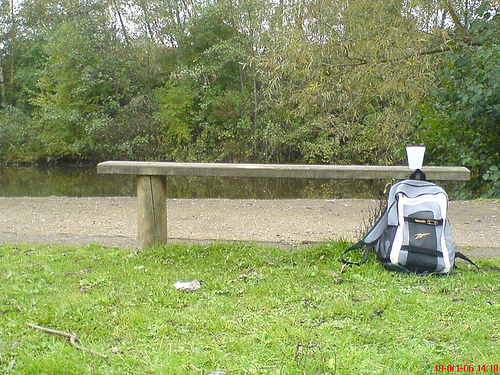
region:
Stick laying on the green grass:
[12, 302, 131, 369]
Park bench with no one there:
[88, 8, 494, 298]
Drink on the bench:
[370, 115, 450, 170]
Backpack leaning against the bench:
[362, 170, 467, 290]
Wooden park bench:
[90, 140, 491, 265]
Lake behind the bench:
[4, 108, 370, 219]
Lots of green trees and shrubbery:
[9, 13, 461, 181]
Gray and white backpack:
[370, 176, 462, 298]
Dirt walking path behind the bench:
[6, 183, 496, 250]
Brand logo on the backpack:
[400, 203, 449, 243]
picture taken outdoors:
[57, 55, 404, 362]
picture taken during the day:
[58, 21, 464, 317]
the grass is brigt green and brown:
[115, 278, 270, 358]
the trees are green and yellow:
[177, 59, 336, 134]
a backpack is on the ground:
[352, 174, 494, 282]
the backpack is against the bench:
[354, 187, 493, 269]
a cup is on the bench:
[387, 79, 424, 169]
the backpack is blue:
[364, 149, 456, 282]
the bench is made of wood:
[101, 143, 248, 288]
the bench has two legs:
[111, 148, 478, 293]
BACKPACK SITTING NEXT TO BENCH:
[350, 176, 465, 281]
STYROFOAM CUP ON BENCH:
[397, 142, 437, 175]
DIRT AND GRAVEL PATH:
[4, 189, 497, 254]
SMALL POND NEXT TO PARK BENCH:
[3, 157, 387, 200]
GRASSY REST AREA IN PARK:
[5, 239, 496, 371]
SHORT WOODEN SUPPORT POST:
[130, 172, 177, 252]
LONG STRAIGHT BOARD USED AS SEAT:
[87, 149, 472, 191]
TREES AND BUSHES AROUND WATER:
[5, 8, 493, 177]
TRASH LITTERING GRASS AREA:
[161, 270, 216, 297]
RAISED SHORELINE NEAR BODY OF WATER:
[40, 155, 97, 172]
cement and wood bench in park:
[82, 142, 474, 277]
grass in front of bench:
[25, 225, 485, 342]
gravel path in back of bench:
[11, 182, 491, 242]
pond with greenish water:
[0, 145, 335, 200]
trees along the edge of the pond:
[1, 0, 492, 150]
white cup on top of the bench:
[386, 131, 456, 171]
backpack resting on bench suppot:
[360, 166, 470, 281]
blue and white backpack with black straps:
[330, 180, 470, 285]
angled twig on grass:
[16, 297, 126, 363]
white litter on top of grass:
[155, 270, 236, 320]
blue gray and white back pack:
[330, 178, 452, 331]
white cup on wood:
[386, 133, 429, 176]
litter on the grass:
[140, 269, 220, 316]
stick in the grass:
[19, 296, 111, 373]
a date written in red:
[424, 358, 479, 373]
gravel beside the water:
[0, 184, 88, 230]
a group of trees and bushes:
[7, 81, 190, 157]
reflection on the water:
[0, 168, 92, 190]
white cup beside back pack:
[344, 133, 466, 324]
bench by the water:
[92, 113, 322, 280]